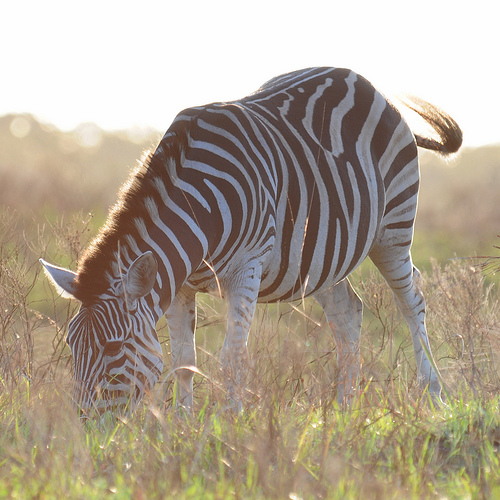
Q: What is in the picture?
A: An animal.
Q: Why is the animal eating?
A: Hungry.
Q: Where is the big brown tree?
A: No tree.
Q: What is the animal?
A: A zebra.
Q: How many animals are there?
A: One.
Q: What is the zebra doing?
A: Eating.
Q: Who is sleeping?
A: No one.